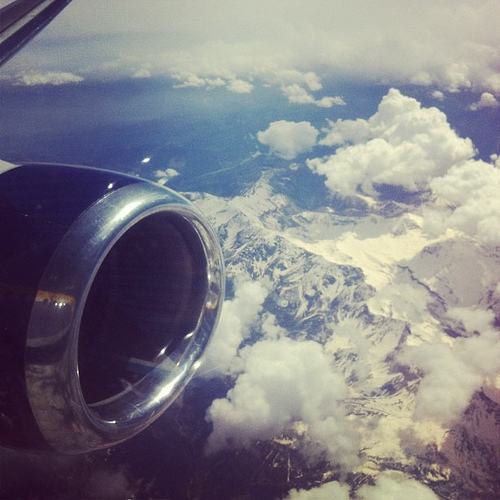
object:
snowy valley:
[262, 200, 478, 315]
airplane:
[1, 0, 225, 454]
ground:
[227, 106, 499, 499]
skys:
[107, 9, 486, 106]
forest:
[151, 91, 252, 152]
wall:
[296, 135, 352, 165]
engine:
[2, 127, 229, 467]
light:
[77, 178, 177, 226]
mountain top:
[266, 179, 376, 337]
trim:
[19, 168, 227, 473]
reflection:
[122, 322, 225, 412]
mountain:
[355, 306, 498, 498]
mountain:
[192, 192, 376, 358]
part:
[0, 1, 76, 92]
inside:
[74, 206, 210, 403]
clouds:
[0, 3, 497, 496]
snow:
[344, 239, 372, 264]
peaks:
[348, 260, 411, 348]